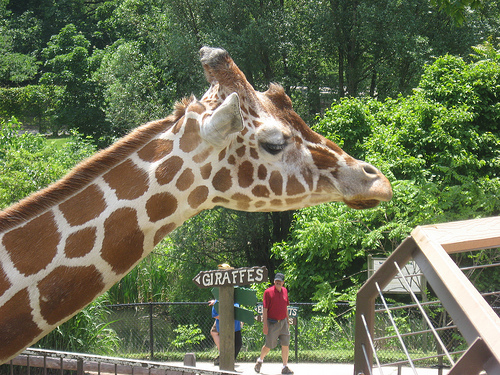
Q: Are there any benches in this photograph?
A: No, there are no benches.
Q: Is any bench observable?
A: No, there are no benches.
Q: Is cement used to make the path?
A: Yes, the path is made of cement.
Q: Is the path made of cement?
A: Yes, the path is made of cement.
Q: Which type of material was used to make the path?
A: The path is made of cement.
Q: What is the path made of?
A: The path is made of concrete.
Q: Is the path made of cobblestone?
A: No, the path is made of concrete.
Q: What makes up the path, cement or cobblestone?
A: The path is made of cement.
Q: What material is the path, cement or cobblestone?
A: The path is made of cement.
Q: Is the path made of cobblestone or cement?
A: The path is made of cement.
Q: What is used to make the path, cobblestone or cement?
A: The path is made of cement.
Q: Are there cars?
A: No, there are no cars.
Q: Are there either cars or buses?
A: No, there are no cars or buses.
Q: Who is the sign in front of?
A: The sign is in front of the man.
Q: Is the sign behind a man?
A: No, the sign is in front of a man.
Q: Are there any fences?
A: Yes, there is a fence.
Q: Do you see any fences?
A: Yes, there is a fence.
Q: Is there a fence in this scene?
A: Yes, there is a fence.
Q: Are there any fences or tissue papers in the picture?
A: Yes, there is a fence.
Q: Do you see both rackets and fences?
A: No, there is a fence but no rackets.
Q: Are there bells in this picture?
A: No, there are no bells.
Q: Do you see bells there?
A: No, there are no bells.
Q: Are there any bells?
A: No, there are no bells.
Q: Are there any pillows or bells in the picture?
A: No, there are no bells or pillows.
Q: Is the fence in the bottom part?
A: Yes, the fence is in the bottom of the image.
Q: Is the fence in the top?
A: No, the fence is in the bottom of the image.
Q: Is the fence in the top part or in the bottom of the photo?
A: The fence is in the bottom of the image.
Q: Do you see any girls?
A: No, there are no girls.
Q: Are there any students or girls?
A: No, there are no girls or students.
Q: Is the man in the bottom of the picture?
A: Yes, the man is in the bottom of the image.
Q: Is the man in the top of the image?
A: No, the man is in the bottom of the image.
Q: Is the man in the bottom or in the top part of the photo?
A: The man is in the bottom of the image.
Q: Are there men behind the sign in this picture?
A: Yes, there is a man behind the sign.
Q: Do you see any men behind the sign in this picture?
A: Yes, there is a man behind the sign.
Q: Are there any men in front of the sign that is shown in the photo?
A: No, the man is behind the sign.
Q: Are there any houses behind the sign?
A: No, there is a man behind the sign.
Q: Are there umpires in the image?
A: No, there are no umpires.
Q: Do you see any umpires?
A: No, there are no umpires.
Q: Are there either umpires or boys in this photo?
A: No, there are no umpires or boys.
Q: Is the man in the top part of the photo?
A: No, the man is in the bottom of the image.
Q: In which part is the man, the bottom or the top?
A: The man is in the bottom of the image.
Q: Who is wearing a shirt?
A: The man is wearing a shirt.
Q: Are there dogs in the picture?
A: No, there are no dogs.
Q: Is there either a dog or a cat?
A: No, there are no dogs or cats.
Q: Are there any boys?
A: No, there are no boys.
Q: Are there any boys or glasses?
A: No, there are no boys or glasses.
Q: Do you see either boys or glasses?
A: No, there are no boys or glasses.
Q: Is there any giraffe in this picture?
A: Yes, there is a giraffe.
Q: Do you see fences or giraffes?
A: Yes, there is a giraffe.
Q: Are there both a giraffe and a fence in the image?
A: Yes, there are both a giraffe and a fence.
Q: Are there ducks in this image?
A: No, there are no ducks.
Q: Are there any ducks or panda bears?
A: No, there are no ducks or panda bears.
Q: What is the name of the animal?
A: The animal is a giraffe.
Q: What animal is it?
A: The animal is a giraffe.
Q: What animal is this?
A: This is a giraffe.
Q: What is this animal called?
A: This is a giraffe.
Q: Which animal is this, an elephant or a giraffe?
A: This is a giraffe.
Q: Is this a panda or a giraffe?
A: This is a giraffe.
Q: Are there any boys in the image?
A: No, there are no boys.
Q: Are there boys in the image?
A: No, there are no boys.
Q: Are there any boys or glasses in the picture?
A: No, there are no boys or glasses.